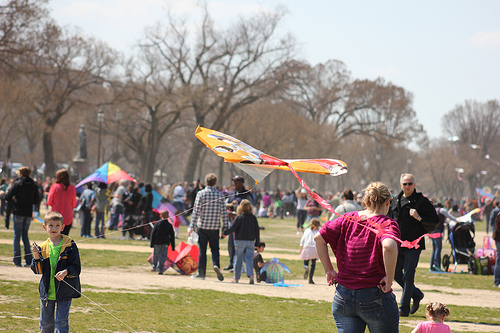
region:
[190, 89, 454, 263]
the kite is multicolored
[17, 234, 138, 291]
the boy is wearing a coat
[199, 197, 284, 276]
the couple is holding hands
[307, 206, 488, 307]
the woman is wearing a pink shirt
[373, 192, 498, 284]
the man is wearing a black jacket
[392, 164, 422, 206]
the man is wearing sunglasses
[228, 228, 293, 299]
the girl is wearing jeans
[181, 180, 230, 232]
the man is wearing plaid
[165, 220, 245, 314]
the man is holding a kite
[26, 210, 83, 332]
a boy wearing jeans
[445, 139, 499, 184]
kites in the air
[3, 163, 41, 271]
a person wearing jeans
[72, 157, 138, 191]
a triangular shape kite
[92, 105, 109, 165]
a light post in the park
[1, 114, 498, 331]
people in the park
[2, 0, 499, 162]
tree line in the background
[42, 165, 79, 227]
a woman wearing blouse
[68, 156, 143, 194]
a colorful kite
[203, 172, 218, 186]
a head of the person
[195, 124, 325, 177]
kite flying over park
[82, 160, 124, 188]
kite flying over park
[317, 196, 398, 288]
red shirt on woman in park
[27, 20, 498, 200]
trees growing around park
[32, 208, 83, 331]
small boy flying kite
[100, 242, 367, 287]
dirt patch on grass ground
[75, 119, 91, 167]
statue on left in park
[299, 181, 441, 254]
red tail of kite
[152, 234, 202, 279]
red kite sitting on ground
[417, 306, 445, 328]
small girl on right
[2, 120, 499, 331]
people in the park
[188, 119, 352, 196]
a kite in the park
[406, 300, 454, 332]
a child walking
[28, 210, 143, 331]
a kid holding string of the kite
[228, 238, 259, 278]
jeans the woman is wearing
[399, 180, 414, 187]
sunglasses the guy is wearing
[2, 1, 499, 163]
trees and lights in the background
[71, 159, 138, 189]
a colorful kite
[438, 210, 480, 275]
stroller in the park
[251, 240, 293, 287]
a kid with his kite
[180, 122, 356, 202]
A kite up in the air.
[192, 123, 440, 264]
A yellow kite up in the air.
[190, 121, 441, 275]
A yellow kite with a pink string.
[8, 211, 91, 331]
A boy flying a kite.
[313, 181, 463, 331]
A woman walking with her daughter.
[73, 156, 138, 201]
A kite in the air.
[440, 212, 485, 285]
A black baby stroller.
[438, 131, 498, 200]
A bunch of kites in the air.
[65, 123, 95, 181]
A statue of a person.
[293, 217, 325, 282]
A little girl running.